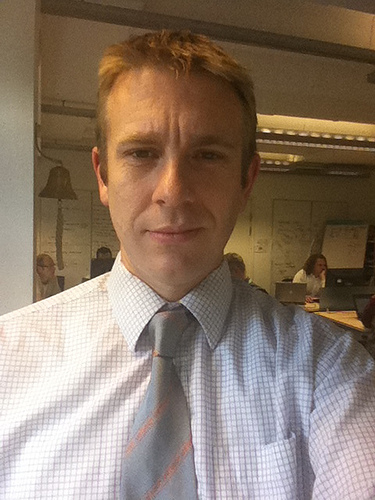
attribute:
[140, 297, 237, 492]
necktie — gray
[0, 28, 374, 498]
white man — standing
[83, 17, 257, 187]
blonde hair — short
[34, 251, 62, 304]
man — bald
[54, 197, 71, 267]
tassel — long, hanging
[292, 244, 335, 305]
man — working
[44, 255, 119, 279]
two men — working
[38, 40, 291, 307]
man — wearing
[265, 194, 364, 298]
whiteboard — behind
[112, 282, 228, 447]
tie — knotted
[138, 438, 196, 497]
stripe — red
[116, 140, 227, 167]
man's eye — tie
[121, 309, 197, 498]
tie — gray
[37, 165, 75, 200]
bell — hanging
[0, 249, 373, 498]
dress shirt — gray, white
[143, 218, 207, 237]
mouth — tie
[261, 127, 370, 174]
lights — overhead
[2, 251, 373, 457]
shirt — small grey, checkered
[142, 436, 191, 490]
stripe — pink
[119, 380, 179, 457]
stripe — pink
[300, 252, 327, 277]
hair — long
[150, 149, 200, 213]
nose — tie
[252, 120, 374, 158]
lights — overhead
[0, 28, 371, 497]
man — behind